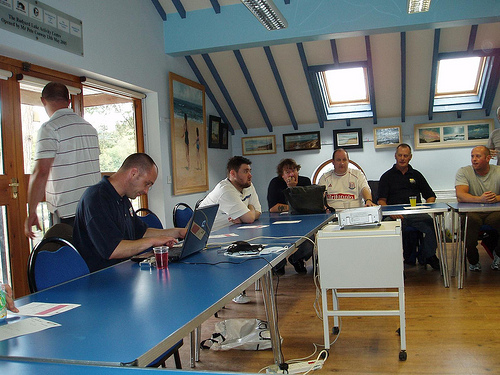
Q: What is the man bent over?
A: Computer.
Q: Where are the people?
A: In a room.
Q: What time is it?
A: Afternoon.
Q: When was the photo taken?
A: During the daytime.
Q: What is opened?
A: The laptop.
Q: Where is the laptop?
A: On table.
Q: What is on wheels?
A: The white stand.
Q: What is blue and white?
A: The ceiling.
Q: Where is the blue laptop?
A: On the table.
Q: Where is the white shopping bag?
A: Under the table.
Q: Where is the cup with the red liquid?
A: Next to the laptop.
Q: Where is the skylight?
A: In the ceiling.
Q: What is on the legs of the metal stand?
A: Wheels.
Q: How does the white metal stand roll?
A: Wheels.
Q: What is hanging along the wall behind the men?
A: Pictures.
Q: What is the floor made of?
A: Wood.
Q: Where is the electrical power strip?
A: Under the table.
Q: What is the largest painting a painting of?
A: People on a beach.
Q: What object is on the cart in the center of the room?
A: Projector.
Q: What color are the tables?
A: Blue.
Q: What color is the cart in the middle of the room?
A: White.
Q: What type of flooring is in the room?
A: Wood.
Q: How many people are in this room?
A: Seven.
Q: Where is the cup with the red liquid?
A: On the left-most table.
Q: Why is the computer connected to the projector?
A: To display the image.